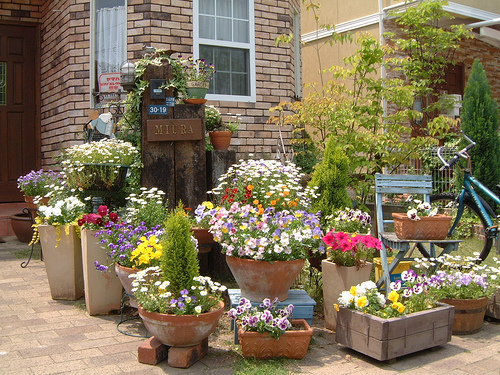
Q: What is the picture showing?
A: It is showing a sidewalk.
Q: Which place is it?
A: It is a sidewalk.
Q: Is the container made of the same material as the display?
A: Yes, both the container and the display are made of wood.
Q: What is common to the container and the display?
A: The material, both the container and the display are wooden.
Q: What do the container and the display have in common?
A: The material, both the container and the display are wooden.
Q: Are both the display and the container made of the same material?
A: Yes, both the display and the container are made of wood.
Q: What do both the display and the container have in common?
A: The material, both the display and the container are wooden.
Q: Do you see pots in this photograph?
A: Yes, there is a pot.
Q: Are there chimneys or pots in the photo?
A: Yes, there is a pot.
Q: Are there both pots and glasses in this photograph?
A: No, there is a pot but no glasses.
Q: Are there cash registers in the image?
A: No, there are no cash registers.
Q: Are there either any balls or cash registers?
A: No, there are no cash registers or balls.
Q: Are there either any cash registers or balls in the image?
A: No, there are no cash registers or balls.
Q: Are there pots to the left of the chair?
A: Yes, there is a pot to the left of the chair.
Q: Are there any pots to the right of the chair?
A: No, the pot is to the left of the chair.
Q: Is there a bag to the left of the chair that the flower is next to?
A: No, there is a pot to the left of the chair.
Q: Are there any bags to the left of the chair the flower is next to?
A: No, there is a pot to the left of the chair.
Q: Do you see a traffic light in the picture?
A: No, there are no traffic lights.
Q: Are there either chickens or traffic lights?
A: No, there are no traffic lights or chickens.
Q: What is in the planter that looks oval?
A: The flowers are in the planter.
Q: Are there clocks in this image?
A: No, there are no clocks.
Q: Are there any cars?
A: No, there are no cars.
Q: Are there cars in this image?
A: No, there are no cars.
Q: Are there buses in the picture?
A: No, there are no buses.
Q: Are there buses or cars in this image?
A: No, there are no buses or cars.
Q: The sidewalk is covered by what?
A: The sidewalk is covered by the bricks.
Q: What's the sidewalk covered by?
A: The sidewalk is covered by the bricks.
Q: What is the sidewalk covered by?
A: The sidewalk is covered by the bricks.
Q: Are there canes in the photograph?
A: No, there are no canes.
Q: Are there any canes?
A: No, there are no canes.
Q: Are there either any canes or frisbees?
A: No, there are no canes or frisbees.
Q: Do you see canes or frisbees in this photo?
A: No, there are no canes or frisbees.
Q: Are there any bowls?
A: No, there are no bowls.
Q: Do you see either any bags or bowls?
A: No, there are no bowls or bags.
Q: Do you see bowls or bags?
A: No, there are no bowls or bags.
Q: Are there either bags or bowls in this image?
A: No, there are no bowls or bags.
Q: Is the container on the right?
A: Yes, the container is on the right of the image.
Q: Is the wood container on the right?
A: Yes, the container is on the right of the image.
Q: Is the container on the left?
A: No, the container is on the right of the image.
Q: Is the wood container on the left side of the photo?
A: No, the container is on the right of the image.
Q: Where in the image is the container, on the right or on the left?
A: The container is on the right of the image.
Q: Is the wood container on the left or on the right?
A: The container is on the right of the image.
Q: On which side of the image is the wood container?
A: The container is on the right of the image.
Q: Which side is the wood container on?
A: The container is on the right of the image.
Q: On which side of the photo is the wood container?
A: The container is on the right of the image.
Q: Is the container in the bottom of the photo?
A: Yes, the container is in the bottom of the image.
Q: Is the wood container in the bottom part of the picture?
A: Yes, the container is in the bottom of the image.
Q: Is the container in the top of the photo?
A: No, the container is in the bottom of the image.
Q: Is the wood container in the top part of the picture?
A: No, the container is in the bottom of the image.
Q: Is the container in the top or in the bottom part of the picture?
A: The container is in the bottom of the image.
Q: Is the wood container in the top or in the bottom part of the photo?
A: The container is in the bottom of the image.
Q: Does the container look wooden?
A: Yes, the container is wooden.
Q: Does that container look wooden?
A: Yes, the container is wooden.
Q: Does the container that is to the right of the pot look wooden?
A: Yes, the container is wooden.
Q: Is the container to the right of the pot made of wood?
A: Yes, the container is made of wood.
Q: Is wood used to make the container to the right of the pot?
A: Yes, the container is made of wood.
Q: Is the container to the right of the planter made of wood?
A: Yes, the container is made of wood.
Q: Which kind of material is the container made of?
A: The container is made of wood.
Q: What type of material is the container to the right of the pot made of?
A: The container is made of wood.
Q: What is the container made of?
A: The container is made of wood.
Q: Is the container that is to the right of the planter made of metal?
A: No, the container is made of wood.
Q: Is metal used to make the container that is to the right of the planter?
A: No, the container is made of wood.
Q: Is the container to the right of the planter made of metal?
A: No, the container is made of wood.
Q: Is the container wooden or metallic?
A: The container is wooden.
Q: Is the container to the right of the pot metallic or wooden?
A: The container is wooden.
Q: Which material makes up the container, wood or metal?
A: The container is made of wood.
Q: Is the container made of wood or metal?
A: The container is made of wood.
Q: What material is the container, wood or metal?
A: The container is made of wood.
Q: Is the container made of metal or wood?
A: The container is made of wood.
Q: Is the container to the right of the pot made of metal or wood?
A: The container is made of wood.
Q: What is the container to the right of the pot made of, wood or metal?
A: The container is made of wood.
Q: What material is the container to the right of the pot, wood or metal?
A: The container is made of wood.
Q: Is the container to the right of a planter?
A: Yes, the container is to the right of a planter.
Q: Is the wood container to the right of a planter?
A: Yes, the container is to the right of a planter.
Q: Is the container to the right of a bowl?
A: No, the container is to the right of a planter.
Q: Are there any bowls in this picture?
A: No, there are no bowls.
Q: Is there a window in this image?
A: Yes, there are windows.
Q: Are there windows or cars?
A: Yes, there are windows.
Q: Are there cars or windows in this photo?
A: Yes, there are windows.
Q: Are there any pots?
A: Yes, there is a pot.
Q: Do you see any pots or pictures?
A: Yes, there is a pot.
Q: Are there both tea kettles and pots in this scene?
A: No, there is a pot but no tea kettles.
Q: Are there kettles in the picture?
A: No, there are no kettles.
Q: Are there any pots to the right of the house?
A: Yes, there is a pot to the right of the house.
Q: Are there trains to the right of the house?
A: No, there is a pot to the right of the house.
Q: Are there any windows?
A: Yes, there is a window.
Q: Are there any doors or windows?
A: Yes, there is a window.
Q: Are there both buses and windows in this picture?
A: No, there is a window but no buses.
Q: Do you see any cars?
A: No, there are no cars.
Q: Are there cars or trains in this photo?
A: No, there are no cars or trains.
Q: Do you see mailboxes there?
A: No, there are no mailboxes.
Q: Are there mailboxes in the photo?
A: No, there are no mailboxes.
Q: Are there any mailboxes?
A: No, there are no mailboxes.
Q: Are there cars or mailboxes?
A: No, there are no mailboxes or cars.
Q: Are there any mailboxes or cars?
A: No, there are no mailboxes or cars.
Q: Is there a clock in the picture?
A: No, there are no clocks.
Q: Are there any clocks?
A: No, there are no clocks.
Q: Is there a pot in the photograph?
A: Yes, there is a pot.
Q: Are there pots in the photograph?
A: Yes, there is a pot.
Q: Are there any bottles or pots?
A: Yes, there is a pot.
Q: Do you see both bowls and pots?
A: No, there is a pot but no bowls.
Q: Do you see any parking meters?
A: No, there are no parking meters.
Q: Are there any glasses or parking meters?
A: No, there are no parking meters or glasses.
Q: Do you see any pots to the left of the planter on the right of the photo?
A: Yes, there is a pot to the left of the planter.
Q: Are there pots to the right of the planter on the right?
A: No, the pot is to the left of the planter.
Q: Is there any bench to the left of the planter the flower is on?
A: No, there is a pot to the left of the planter.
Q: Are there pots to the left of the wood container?
A: Yes, there is a pot to the left of the container.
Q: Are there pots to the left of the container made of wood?
A: Yes, there is a pot to the left of the container.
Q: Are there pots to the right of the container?
A: No, the pot is to the left of the container.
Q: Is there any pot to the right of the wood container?
A: No, the pot is to the left of the container.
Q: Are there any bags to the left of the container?
A: No, there is a pot to the left of the container.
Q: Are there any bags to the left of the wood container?
A: No, there is a pot to the left of the container.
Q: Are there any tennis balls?
A: No, there are no tennis balls.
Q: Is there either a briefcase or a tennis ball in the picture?
A: No, there are no tennis balls or briefcases.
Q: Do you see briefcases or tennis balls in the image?
A: No, there are no tennis balls or briefcases.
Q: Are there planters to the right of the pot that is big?
A: No, the planter is to the left of the pot.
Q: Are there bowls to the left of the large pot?
A: No, there is a planter to the left of the pot.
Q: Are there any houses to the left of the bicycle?
A: Yes, there is a house to the left of the bicycle.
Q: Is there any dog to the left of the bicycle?
A: No, there is a house to the left of the bicycle.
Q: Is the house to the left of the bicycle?
A: Yes, the house is to the left of the bicycle.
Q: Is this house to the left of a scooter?
A: No, the house is to the left of the bicycle.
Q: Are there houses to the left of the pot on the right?
A: Yes, there is a house to the left of the pot.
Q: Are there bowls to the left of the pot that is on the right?
A: No, there is a house to the left of the pot.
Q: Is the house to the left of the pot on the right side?
A: Yes, the house is to the left of the pot.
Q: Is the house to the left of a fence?
A: No, the house is to the left of the pot.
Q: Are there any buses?
A: No, there are no buses.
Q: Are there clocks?
A: No, there are no clocks.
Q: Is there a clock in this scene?
A: No, there are no clocks.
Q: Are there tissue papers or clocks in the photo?
A: No, there are no clocks or tissue papers.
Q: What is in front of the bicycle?
A: The flowers are in front of the bicycle.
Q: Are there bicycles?
A: Yes, there is a bicycle.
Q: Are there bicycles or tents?
A: Yes, there is a bicycle.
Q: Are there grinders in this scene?
A: No, there are no grinders.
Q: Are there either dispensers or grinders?
A: No, there are no grinders or dispensers.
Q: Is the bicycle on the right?
A: Yes, the bicycle is on the right of the image.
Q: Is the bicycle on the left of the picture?
A: No, the bicycle is on the right of the image.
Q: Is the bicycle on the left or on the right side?
A: The bicycle is on the right of the image.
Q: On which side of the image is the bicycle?
A: The bicycle is on the right of the image.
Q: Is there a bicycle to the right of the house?
A: Yes, there is a bicycle to the right of the house.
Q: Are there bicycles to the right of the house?
A: Yes, there is a bicycle to the right of the house.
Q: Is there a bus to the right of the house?
A: No, there is a bicycle to the right of the house.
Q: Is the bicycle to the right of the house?
A: Yes, the bicycle is to the right of the house.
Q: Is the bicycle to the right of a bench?
A: No, the bicycle is to the right of the house.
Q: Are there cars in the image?
A: No, there are no cars.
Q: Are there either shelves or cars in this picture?
A: No, there are no cars or shelves.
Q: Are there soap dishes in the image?
A: No, there are no soap dishes.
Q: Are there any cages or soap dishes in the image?
A: No, there are no soap dishes or cages.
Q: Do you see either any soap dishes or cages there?
A: No, there are no soap dishes or cages.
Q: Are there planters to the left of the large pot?
A: Yes, there is a planter to the left of the pot.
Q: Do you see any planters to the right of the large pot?
A: No, the planter is to the left of the pot.